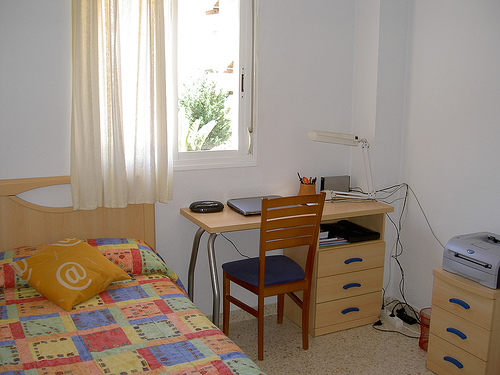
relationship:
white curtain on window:
[66, 1, 175, 203] [105, 6, 254, 157]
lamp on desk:
[307, 129, 375, 200] [177, 186, 393, 335]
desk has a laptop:
[177, 186, 393, 335] [226, 193, 286, 220]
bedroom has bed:
[3, 142, 272, 372] [4, 173, 256, 374]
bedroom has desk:
[3, 142, 272, 372] [177, 186, 393, 335]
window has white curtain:
[81, 1, 255, 169] [70, 1, 180, 210]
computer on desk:
[209, 172, 344, 213] [165, 161, 405, 346]